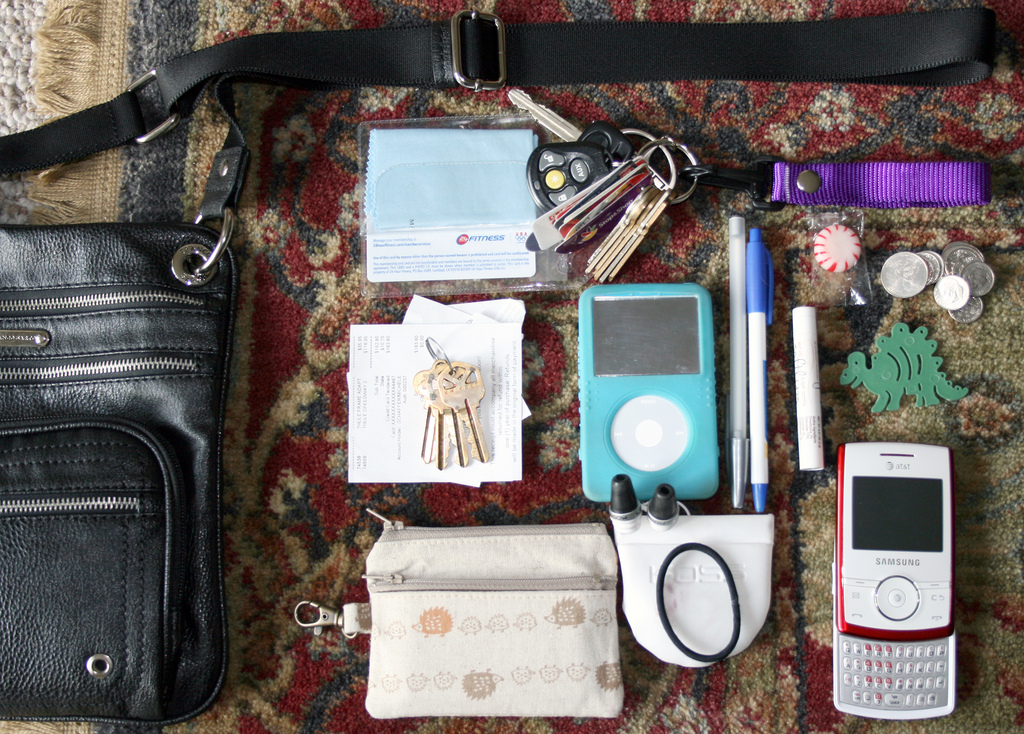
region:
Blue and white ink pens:
[728, 217, 771, 513]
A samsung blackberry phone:
[836, 438, 964, 720]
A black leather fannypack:
[3, 12, 244, 714]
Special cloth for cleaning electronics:
[360, 122, 580, 291]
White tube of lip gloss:
[789, 305, 829, 474]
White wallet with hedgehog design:
[302, 508, 634, 718]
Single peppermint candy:
[811, 211, 881, 307]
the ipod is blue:
[577, 286, 718, 496]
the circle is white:
[608, 396, 689, 470]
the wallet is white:
[370, 524, 626, 714]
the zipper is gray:
[362, 571, 618, 588]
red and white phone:
[836, 444, 961, 720]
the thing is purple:
[769, 164, 986, 199]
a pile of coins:
[877, 238, 994, 324]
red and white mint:
[814, 221, 859, 278]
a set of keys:
[503, 91, 700, 281]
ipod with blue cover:
[567, 262, 732, 498]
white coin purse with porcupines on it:
[330, 495, 624, 731]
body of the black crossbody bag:
[1, 192, 262, 727]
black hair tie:
[653, 528, 746, 669]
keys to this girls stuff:
[504, 88, 711, 279]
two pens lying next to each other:
[715, 205, 785, 516]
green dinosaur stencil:
[835, 309, 992, 418]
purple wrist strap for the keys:
[763, 135, 1002, 228]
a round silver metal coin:
[918, 275, 972, 310]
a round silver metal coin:
[965, 262, 998, 295]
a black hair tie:
[661, 532, 744, 660]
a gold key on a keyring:
[435, 361, 493, 460]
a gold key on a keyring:
[415, 364, 453, 462]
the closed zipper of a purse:
[2, 493, 149, 516]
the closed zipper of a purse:
[4, 354, 201, 378]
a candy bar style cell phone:
[830, 440, 963, 723]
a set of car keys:
[411, 334, 487, 470]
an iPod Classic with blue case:
[569, 279, 721, 504]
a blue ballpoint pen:
[745, 228, 772, 514]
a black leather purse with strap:
[2, 13, 1018, 723]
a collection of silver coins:
[881, 241, 996, 327]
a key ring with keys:
[501, 87, 989, 284]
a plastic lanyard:
[348, 115, 570, 293]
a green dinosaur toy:
[836, 324, 976, 410]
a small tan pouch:
[356, 506, 625, 721]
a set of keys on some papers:
[409, 339, 487, 472]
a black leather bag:
[0, 5, 997, 721]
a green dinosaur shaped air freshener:
[838, 326, 968, 415]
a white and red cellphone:
[830, 441, 955, 723]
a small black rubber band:
[656, 542, 739, 664]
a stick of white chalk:
[792, 302, 825, 476]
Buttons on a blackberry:
[823, 615, 966, 723]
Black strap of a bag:
[0, 1, 1015, 223]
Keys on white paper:
[314, 267, 550, 503]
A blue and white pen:
[716, 201, 787, 538]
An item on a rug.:
[318, 516, 619, 719]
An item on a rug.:
[790, 295, 829, 482]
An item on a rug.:
[841, 326, 962, 416]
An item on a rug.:
[746, 228, 776, 511]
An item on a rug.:
[718, 217, 747, 493]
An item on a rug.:
[503, 84, 993, 247]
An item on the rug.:
[743, 225, 766, 507]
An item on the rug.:
[720, 219, 753, 505]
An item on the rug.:
[793, 305, 833, 484]